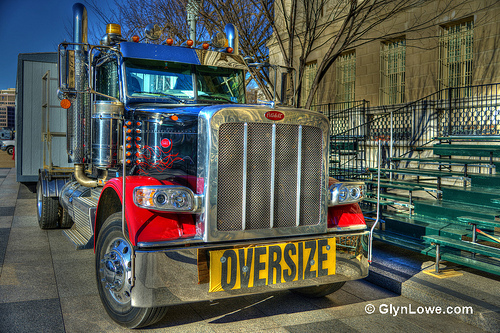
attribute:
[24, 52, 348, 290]
truck — parked, red, large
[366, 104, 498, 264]
bleachers — green, set, silver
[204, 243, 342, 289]
sign — yellow, black, oversized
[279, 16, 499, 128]
building — tall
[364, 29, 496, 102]
windows — large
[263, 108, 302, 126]
logo — red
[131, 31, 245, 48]
lights — orange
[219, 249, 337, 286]
writing — black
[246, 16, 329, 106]
tree — bare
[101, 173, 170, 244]
cover — red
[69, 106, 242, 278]
diesel — loaded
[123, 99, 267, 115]
hood — black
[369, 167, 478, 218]
benches — green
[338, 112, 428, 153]
railing — black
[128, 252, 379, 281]
bumper — silver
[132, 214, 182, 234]
paint — red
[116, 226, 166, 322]
wheel — large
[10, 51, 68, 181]
trailer — gray, white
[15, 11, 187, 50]
sky — clear, blue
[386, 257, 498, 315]
sidewalk — gray, black, tiled